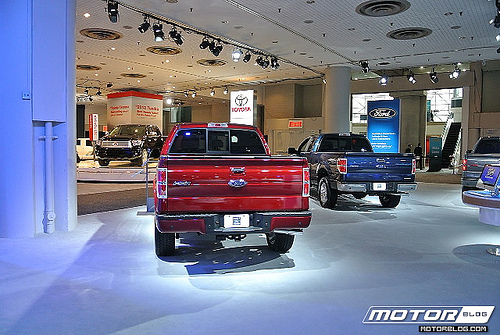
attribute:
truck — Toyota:
[89, 120, 163, 170]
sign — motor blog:
[361, 303, 499, 328]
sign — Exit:
[273, 112, 324, 142]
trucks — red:
[128, 120, 433, 263]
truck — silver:
[458, 131, 499, 193]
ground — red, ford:
[390, 101, 440, 147]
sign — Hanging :
[367, 97, 402, 154]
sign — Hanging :
[230, 89, 255, 126]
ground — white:
[350, 92, 406, 142]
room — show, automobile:
[90, 0, 499, 295]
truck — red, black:
[146, 118, 317, 255]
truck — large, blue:
[292, 126, 427, 220]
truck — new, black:
[97, 122, 181, 167]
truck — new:
[150, 120, 313, 265]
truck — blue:
[292, 130, 421, 210]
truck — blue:
[302, 132, 398, 217]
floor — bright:
[256, 252, 358, 319]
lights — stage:
[132, 4, 304, 87]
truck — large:
[130, 86, 336, 286]